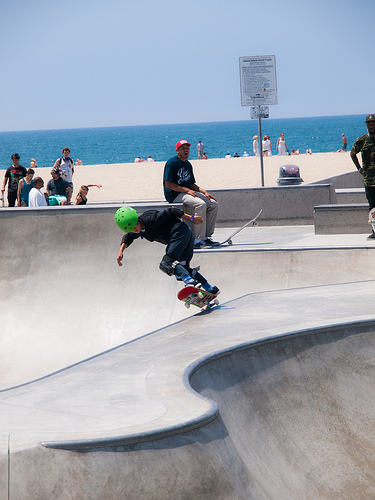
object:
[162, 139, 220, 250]
man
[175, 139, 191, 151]
hat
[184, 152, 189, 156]
mouth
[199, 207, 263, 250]
skateboard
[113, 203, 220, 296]
child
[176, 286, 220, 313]
skateboard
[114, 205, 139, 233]
helmet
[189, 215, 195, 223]
watch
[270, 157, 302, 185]
trash can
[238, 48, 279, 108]
sign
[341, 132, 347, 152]
man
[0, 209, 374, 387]
ramp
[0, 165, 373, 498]
park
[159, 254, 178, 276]
guards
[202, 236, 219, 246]
foot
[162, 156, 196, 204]
shirt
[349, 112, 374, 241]
man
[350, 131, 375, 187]
shirt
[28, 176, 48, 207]
people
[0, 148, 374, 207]
beach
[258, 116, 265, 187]
pole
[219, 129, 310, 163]
crowd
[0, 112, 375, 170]
ocean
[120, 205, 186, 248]
shirt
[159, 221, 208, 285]
pants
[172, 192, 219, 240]
pants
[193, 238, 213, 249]
shoes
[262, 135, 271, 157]
woman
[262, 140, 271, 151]
shirt